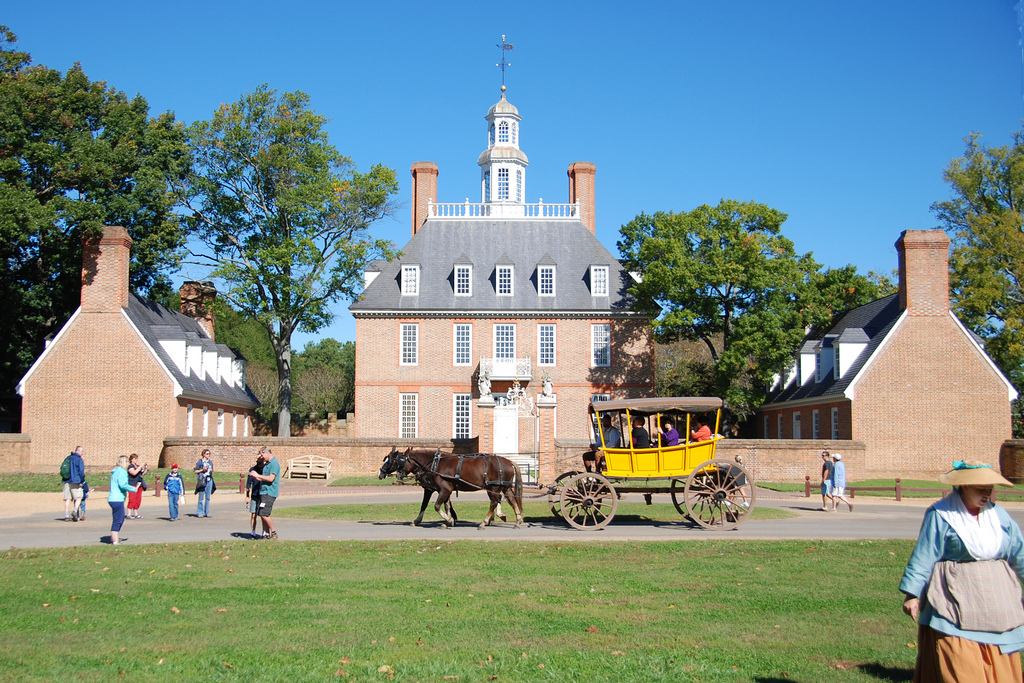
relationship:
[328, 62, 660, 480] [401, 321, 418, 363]
brick building has window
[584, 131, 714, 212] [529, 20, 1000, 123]
clouds in sky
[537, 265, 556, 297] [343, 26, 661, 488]
window on brick building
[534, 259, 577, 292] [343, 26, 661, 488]
window in front of brick building